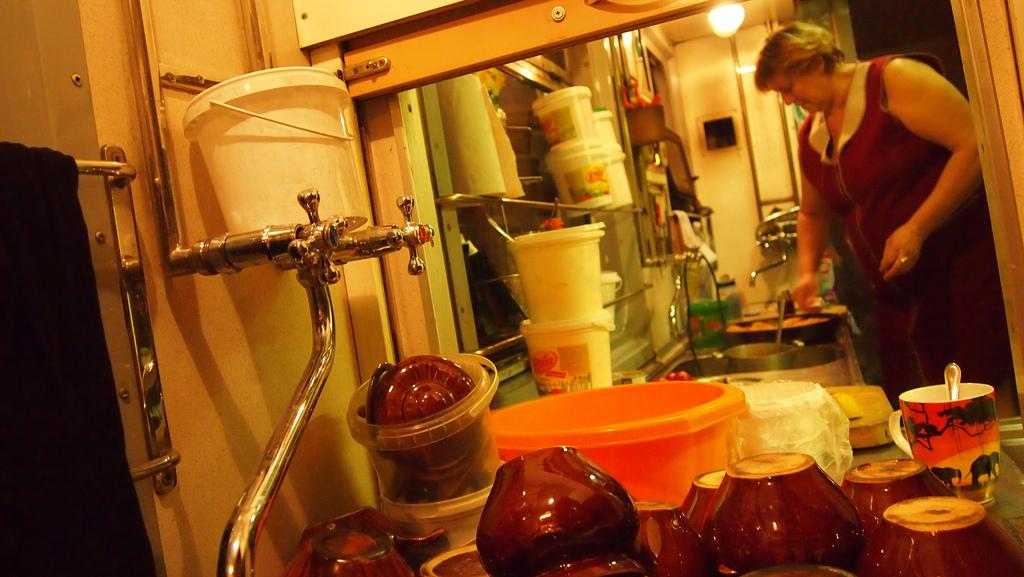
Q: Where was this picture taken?
A: In a kitchen.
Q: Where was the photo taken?
A: In a kitchen.